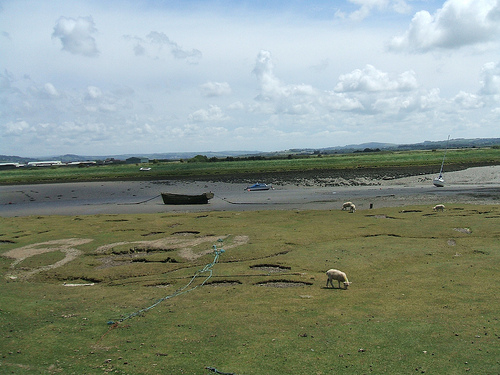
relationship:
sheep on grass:
[323, 264, 358, 298] [5, 154, 497, 374]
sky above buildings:
[3, 1, 500, 146] [3, 156, 103, 169]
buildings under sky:
[3, 156, 103, 169] [3, 1, 500, 146]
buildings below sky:
[3, 156, 103, 169] [3, 1, 500, 146]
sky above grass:
[3, 1, 500, 146] [5, 154, 497, 374]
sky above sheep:
[3, 1, 500, 146] [323, 264, 358, 298]